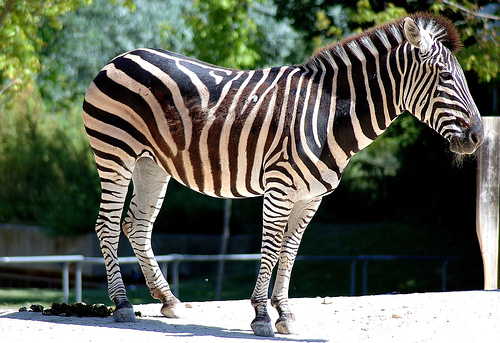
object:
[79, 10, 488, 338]
zebra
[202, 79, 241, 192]
stripes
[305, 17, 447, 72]
mane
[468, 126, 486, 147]
nose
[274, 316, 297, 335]
hoof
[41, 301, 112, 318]
droppings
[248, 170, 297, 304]
leg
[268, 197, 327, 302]
leg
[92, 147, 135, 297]
leg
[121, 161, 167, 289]
leg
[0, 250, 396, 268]
hand railing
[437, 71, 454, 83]
eye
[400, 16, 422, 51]
ear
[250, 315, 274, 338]
hoof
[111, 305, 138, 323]
hoof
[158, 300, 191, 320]
hoof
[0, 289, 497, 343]
floor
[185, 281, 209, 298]
shade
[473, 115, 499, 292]
pole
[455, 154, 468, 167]
whiskers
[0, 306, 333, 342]
shadow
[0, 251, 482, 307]
pen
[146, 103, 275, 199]
belly